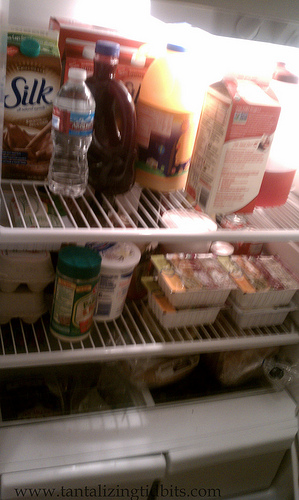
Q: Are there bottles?
A: Yes, there is a bottle.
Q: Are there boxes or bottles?
A: Yes, there is a bottle.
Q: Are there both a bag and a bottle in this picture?
A: No, there is a bottle but no bags.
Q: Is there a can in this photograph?
A: No, there are no cans.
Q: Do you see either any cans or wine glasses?
A: No, there are no cans or wine glasses.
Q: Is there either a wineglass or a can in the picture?
A: No, there are no cans or wine glasses.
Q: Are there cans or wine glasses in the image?
A: No, there are no cans or wine glasses.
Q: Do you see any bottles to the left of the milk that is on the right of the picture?
A: Yes, there is a bottle to the left of the milk.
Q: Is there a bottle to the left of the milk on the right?
A: Yes, there is a bottle to the left of the milk.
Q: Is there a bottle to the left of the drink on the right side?
A: Yes, there is a bottle to the left of the milk.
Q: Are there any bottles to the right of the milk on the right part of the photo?
A: No, the bottle is to the left of the milk.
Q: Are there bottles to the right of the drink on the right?
A: No, the bottle is to the left of the milk.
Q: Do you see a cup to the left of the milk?
A: No, there is a bottle to the left of the milk.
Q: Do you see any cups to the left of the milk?
A: No, there is a bottle to the left of the milk.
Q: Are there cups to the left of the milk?
A: No, there is a bottle to the left of the milk.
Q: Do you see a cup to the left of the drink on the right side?
A: No, there is a bottle to the left of the milk.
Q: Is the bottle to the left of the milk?
A: Yes, the bottle is to the left of the milk.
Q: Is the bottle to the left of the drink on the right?
A: Yes, the bottle is to the left of the milk.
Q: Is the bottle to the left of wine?
A: No, the bottle is to the left of the milk.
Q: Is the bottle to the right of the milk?
A: No, the bottle is to the left of the milk.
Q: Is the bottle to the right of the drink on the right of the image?
A: No, the bottle is to the left of the milk.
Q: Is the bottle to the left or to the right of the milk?
A: The bottle is to the left of the milk.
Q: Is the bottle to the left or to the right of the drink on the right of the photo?
A: The bottle is to the left of the milk.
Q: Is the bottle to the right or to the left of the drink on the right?
A: The bottle is to the left of the milk.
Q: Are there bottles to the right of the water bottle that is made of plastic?
A: Yes, there is a bottle to the right of the water bottle.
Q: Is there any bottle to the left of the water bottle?
A: No, the bottle is to the right of the water bottle.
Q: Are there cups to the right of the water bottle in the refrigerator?
A: No, there is a bottle to the right of the water bottle.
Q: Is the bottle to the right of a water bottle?
A: Yes, the bottle is to the right of a water bottle.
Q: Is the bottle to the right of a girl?
A: No, the bottle is to the right of a water bottle.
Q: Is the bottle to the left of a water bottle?
A: No, the bottle is to the right of a water bottle.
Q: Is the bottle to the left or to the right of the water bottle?
A: The bottle is to the right of the water bottle.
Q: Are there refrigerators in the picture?
A: Yes, there is a refrigerator.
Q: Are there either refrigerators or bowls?
A: Yes, there is a refrigerator.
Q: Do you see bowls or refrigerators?
A: Yes, there is a refrigerator.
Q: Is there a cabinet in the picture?
A: No, there are no cabinets.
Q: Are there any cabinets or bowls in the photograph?
A: No, there are no cabinets or bowls.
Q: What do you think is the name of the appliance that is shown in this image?
A: The appliance is a refrigerator.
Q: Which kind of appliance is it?
A: The appliance is a refrigerator.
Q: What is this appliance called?
A: This is a refrigerator.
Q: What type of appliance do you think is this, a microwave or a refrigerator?
A: This is a refrigerator.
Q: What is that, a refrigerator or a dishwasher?
A: That is a refrigerator.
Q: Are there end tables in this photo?
A: No, there are no end tables.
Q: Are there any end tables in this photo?
A: No, there are no end tables.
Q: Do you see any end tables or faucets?
A: No, there are no end tables or faucets.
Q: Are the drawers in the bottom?
A: Yes, the drawers are in the bottom of the image.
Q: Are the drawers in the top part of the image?
A: No, the drawers are in the bottom of the image.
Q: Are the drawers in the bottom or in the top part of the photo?
A: The drawers are in the bottom of the image.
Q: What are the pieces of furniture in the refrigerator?
A: The pieces of furniture are drawers.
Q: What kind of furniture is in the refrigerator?
A: The pieces of furniture are drawers.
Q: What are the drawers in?
A: The drawers are in the refrigerator.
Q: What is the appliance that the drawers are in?
A: The appliance is a refrigerator.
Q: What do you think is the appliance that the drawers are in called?
A: The appliance is a refrigerator.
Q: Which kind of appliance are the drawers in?
A: The drawers are in the freezer.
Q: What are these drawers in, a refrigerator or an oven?
A: The drawers are in a refrigerator.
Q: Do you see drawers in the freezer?
A: Yes, there are drawers in the freezer.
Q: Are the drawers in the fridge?
A: Yes, the drawers are in the fridge.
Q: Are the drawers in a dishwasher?
A: No, the drawers are in the fridge.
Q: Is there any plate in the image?
A: No, there are no plates.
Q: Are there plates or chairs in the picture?
A: No, there are no plates or chairs.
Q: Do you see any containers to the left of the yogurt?
A: Yes, there is a container to the left of the yogurt.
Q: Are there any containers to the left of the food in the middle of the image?
A: Yes, there is a container to the left of the yogurt.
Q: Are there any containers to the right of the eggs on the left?
A: Yes, there is a container to the right of the eggs.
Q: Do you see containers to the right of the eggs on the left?
A: Yes, there is a container to the right of the eggs.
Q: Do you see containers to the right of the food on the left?
A: Yes, there is a container to the right of the eggs.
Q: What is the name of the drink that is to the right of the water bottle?
A: The drink is juice.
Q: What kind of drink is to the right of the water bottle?
A: The drink is juice.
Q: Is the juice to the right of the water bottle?
A: Yes, the juice is to the right of the water bottle.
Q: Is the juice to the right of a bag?
A: No, the juice is to the right of the water bottle.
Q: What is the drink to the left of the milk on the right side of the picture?
A: The drink is juice.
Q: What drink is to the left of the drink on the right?
A: The drink is juice.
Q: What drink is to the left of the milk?
A: The drink is juice.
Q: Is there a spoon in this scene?
A: No, there are no spoons.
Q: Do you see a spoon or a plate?
A: No, there are no spoons or plates.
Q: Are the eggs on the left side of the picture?
A: Yes, the eggs are on the left of the image.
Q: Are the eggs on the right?
A: No, the eggs are on the left of the image.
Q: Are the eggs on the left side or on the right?
A: The eggs are on the left of the image.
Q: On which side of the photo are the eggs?
A: The eggs are on the left of the image.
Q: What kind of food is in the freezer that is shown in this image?
A: The food is eggs.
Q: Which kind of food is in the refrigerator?
A: The food is eggs.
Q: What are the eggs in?
A: The eggs are in the fridge.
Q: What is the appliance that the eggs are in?
A: The appliance is a refrigerator.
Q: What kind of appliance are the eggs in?
A: The eggs are in the refrigerator.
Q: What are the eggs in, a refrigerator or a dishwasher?
A: The eggs are in a refrigerator.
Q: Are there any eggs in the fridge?
A: Yes, there are eggs in the fridge.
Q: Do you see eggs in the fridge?
A: Yes, there are eggs in the fridge.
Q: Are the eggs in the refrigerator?
A: Yes, the eggs are in the refrigerator.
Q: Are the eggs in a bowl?
A: No, the eggs are in the refrigerator.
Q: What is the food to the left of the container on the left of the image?
A: The food is eggs.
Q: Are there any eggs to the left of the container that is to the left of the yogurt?
A: Yes, there are eggs to the left of the container.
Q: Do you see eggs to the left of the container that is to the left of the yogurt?
A: Yes, there are eggs to the left of the container.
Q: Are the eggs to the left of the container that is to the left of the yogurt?
A: Yes, the eggs are to the left of the container.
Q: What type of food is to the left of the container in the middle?
A: The food is eggs.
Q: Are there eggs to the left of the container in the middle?
A: Yes, there are eggs to the left of the container.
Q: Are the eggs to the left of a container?
A: Yes, the eggs are to the left of a container.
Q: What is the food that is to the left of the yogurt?
A: The food is eggs.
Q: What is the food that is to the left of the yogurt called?
A: The food is eggs.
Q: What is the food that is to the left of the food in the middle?
A: The food is eggs.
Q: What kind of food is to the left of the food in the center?
A: The food is eggs.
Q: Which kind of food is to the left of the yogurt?
A: The food is eggs.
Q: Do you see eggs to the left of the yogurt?
A: Yes, there are eggs to the left of the yogurt.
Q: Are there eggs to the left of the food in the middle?
A: Yes, there are eggs to the left of the yogurt.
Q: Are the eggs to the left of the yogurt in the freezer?
A: Yes, the eggs are to the left of the yogurt.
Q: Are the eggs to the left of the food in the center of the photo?
A: Yes, the eggs are to the left of the yogurt.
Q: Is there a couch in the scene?
A: No, there are no couches.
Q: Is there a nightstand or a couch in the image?
A: No, there are no couches or nightstands.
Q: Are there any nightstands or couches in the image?
A: No, there are no couches or nightstands.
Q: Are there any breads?
A: Yes, there is a bread.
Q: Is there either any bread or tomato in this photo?
A: Yes, there is a bread.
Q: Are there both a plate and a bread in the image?
A: No, there is a bread but no plates.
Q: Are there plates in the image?
A: No, there are no plates.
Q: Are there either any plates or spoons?
A: No, there are no plates or spoons.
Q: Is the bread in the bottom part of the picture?
A: Yes, the bread is in the bottom of the image.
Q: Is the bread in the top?
A: No, the bread is in the bottom of the image.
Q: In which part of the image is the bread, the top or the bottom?
A: The bread is in the bottom of the image.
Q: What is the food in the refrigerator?
A: The food is a bread.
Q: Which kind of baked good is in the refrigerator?
A: The food is a bread.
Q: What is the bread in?
A: The bread is in the fridge.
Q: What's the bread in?
A: The bread is in the fridge.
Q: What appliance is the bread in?
A: The bread is in the fridge.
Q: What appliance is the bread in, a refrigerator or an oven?
A: The bread is in a refrigerator.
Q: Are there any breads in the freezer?
A: Yes, there is a bread in the freezer.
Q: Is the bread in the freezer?
A: Yes, the bread is in the freezer.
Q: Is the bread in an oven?
A: No, the bread is in the freezer.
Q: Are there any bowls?
A: No, there are no bowls.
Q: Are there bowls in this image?
A: No, there are no bowls.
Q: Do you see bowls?
A: No, there are no bowls.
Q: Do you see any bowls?
A: No, there are no bowls.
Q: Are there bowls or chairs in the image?
A: No, there are no bowls or chairs.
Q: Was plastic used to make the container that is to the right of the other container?
A: Yes, the container is made of plastic.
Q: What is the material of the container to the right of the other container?
A: The container is made of plastic.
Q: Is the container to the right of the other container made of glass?
A: No, the container is made of plastic.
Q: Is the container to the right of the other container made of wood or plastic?
A: The container is made of plastic.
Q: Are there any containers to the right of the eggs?
A: Yes, there is a container to the right of the eggs.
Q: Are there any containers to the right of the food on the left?
A: Yes, there is a container to the right of the eggs.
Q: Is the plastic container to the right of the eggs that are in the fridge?
A: Yes, the container is to the right of the eggs.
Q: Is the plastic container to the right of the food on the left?
A: Yes, the container is to the right of the eggs.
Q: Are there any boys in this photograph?
A: No, there are no boys.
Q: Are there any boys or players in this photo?
A: No, there are no boys or players.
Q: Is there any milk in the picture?
A: Yes, there is milk.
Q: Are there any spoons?
A: No, there are no spoons.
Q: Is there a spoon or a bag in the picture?
A: No, there are no spoons or bags.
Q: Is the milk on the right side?
A: Yes, the milk is on the right of the image.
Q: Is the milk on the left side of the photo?
A: No, the milk is on the right of the image.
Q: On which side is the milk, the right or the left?
A: The milk is on the right of the image.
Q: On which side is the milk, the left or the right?
A: The milk is on the right of the image.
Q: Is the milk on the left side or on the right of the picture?
A: The milk is on the right of the image.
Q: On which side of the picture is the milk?
A: The milk is on the right of the image.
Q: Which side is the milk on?
A: The milk is on the right of the image.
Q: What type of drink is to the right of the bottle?
A: The drink is milk.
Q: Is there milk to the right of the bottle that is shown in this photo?
A: Yes, there is milk to the right of the bottle.